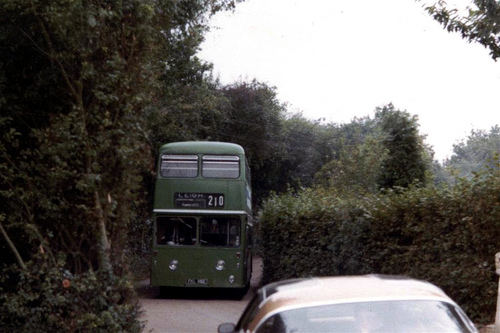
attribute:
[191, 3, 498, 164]
sky — gray and cloudy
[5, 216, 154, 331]
shrub — green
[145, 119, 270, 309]
bus — green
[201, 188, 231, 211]
numbers — white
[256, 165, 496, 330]
hedge — green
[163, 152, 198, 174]
blind — white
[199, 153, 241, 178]
blind — white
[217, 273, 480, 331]
car — brown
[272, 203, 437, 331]
bush — green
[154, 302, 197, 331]
pavement — light gray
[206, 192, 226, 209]
writing — white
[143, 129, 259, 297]
bus — green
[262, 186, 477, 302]
hedge — green